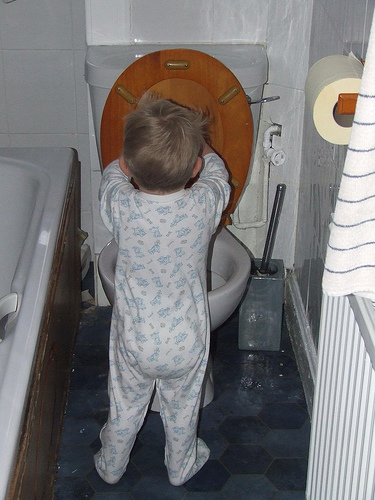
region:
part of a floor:
[244, 457, 249, 478]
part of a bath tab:
[23, 413, 31, 448]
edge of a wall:
[305, 306, 318, 346]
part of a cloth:
[172, 416, 182, 437]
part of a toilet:
[229, 287, 233, 295]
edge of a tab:
[36, 331, 50, 362]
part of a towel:
[331, 284, 333, 300]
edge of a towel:
[334, 240, 351, 276]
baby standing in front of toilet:
[96, 96, 235, 482]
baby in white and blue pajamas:
[94, 91, 233, 485]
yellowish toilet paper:
[302, 50, 367, 146]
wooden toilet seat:
[96, 47, 255, 229]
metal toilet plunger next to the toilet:
[233, 182, 289, 353]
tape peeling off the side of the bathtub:
[74, 227, 95, 306]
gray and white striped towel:
[314, 0, 374, 302]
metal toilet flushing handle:
[243, 90, 281, 108]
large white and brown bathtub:
[0, 145, 77, 499]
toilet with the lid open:
[91, 46, 257, 333]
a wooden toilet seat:
[100, 46, 252, 228]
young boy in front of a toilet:
[89, 99, 214, 483]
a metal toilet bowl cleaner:
[234, 183, 282, 354]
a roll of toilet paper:
[305, 55, 373, 144]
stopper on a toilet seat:
[113, 84, 138, 104]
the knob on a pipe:
[266, 147, 285, 166]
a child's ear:
[118, 154, 130, 176]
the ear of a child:
[188, 156, 203, 180]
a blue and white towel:
[323, 17, 373, 298]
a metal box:
[239, 258, 285, 348]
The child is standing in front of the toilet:
[96, 99, 231, 486]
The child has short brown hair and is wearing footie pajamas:
[100, 95, 241, 494]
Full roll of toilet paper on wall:
[307, 53, 365, 146]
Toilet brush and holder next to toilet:
[235, 181, 290, 356]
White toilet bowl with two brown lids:
[85, 42, 270, 410]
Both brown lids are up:
[97, 50, 253, 231]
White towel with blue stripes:
[321, 7, 374, 298]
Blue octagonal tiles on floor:
[57, 278, 308, 497]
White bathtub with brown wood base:
[2, 142, 88, 495]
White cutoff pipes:
[232, 123, 289, 232]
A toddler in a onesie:
[93, 98, 232, 485]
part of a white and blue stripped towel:
[321, 6, 374, 296]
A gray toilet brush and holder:
[237, 183, 283, 352]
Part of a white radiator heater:
[304, 292, 374, 497]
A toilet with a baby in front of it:
[83, 43, 252, 413]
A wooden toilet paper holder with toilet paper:
[302, 51, 363, 145]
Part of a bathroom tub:
[1, 146, 79, 499]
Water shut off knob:
[265, 147, 285, 167]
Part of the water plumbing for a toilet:
[232, 125, 284, 230]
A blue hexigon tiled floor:
[51, 260, 310, 498]